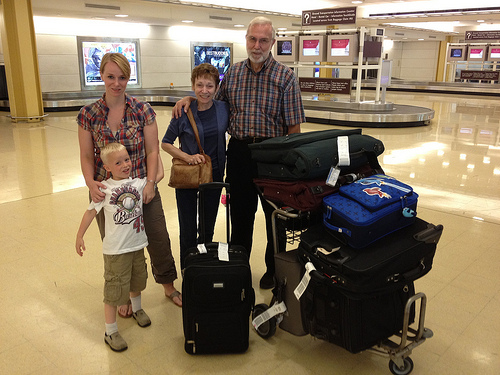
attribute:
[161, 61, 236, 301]
lady — with blond hair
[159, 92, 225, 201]
leather handbag — brown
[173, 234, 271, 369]
piece of luggage — black, with handle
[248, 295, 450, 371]
luggage on wheels —  black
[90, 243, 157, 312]
boy's shorts — brown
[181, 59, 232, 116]
woman's hair — short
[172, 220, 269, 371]
luggage — tagged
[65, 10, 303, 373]
group of four — standing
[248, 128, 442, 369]
cart with luggage — stacked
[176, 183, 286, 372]
black luggage — pulled up